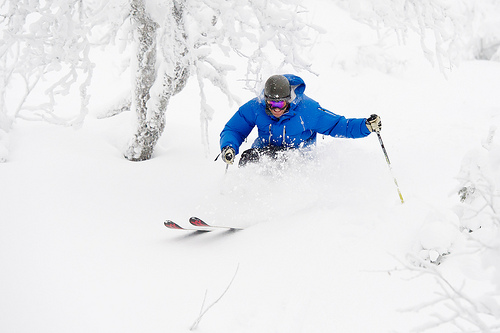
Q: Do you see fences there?
A: No, there are no fences.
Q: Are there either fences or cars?
A: No, there are no fences or cars.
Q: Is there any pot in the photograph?
A: No, there are no pots.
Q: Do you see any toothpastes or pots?
A: No, there are no pots or toothpastes.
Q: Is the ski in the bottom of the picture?
A: Yes, the ski is in the bottom of the image.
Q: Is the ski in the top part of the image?
A: No, the ski is in the bottom of the image.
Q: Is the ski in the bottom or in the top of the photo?
A: The ski is in the bottom of the image.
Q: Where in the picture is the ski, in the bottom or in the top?
A: The ski is in the bottom of the image.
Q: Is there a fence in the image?
A: No, there are no fences.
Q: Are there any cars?
A: No, there are no cars.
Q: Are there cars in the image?
A: No, there are no cars.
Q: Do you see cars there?
A: No, there are no cars.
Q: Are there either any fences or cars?
A: No, there are no cars or fences.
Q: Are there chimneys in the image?
A: No, there are no chimneys.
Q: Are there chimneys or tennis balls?
A: No, there are no chimneys or tennis balls.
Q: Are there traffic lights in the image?
A: No, there are no traffic lights.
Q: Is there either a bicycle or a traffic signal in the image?
A: No, there are no traffic lights or bicycles.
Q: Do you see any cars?
A: No, there are no cars.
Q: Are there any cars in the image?
A: No, there are no cars.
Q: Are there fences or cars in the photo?
A: No, there are no cars or fences.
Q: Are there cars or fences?
A: No, there are no cars or fences.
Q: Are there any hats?
A: Yes, there is a hat.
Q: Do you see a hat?
A: Yes, there is a hat.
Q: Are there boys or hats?
A: Yes, there is a hat.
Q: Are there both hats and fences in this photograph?
A: No, there is a hat but no fences.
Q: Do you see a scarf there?
A: No, there are no scarves.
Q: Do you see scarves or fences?
A: No, there are no scarves or fences.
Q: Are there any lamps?
A: No, there are no lamps.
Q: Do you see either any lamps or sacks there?
A: No, there are no lamps or sacks.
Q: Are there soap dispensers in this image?
A: No, there are no soap dispensers.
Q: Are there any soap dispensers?
A: No, there are no soap dispensers.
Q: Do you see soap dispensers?
A: No, there are no soap dispensers.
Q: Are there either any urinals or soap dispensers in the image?
A: No, there are no soap dispensers or urinals.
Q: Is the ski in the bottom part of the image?
A: Yes, the ski is in the bottom of the image.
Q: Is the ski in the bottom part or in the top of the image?
A: The ski is in the bottom of the image.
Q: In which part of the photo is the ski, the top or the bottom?
A: The ski is in the bottom of the image.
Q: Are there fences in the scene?
A: No, there are no fences.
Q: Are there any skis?
A: Yes, there are skis.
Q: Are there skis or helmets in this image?
A: Yes, there are skis.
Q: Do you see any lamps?
A: No, there are no lamps.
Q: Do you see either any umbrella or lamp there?
A: No, there are no lamps or umbrellas.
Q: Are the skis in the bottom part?
A: Yes, the skis are in the bottom of the image.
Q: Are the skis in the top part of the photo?
A: No, the skis are in the bottom of the image.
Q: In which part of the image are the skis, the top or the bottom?
A: The skis are in the bottom of the image.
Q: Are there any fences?
A: No, there are no fences.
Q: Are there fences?
A: No, there are no fences.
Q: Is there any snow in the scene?
A: Yes, there is snow.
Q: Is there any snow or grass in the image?
A: Yes, there is snow.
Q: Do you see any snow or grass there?
A: Yes, there is snow.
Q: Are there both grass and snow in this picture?
A: No, there is snow but no grass.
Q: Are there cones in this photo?
A: No, there are no cones.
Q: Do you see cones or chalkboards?
A: No, there are no cones or chalkboards.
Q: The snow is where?
A: The snow is on the ground.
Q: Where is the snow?
A: The snow is on the ground.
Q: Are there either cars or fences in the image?
A: No, there are no fences or cars.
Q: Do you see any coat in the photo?
A: Yes, there is a coat.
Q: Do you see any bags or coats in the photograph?
A: Yes, there is a coat.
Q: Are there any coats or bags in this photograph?
A: Yes, there is a coat.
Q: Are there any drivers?
A: No, there are no drivers.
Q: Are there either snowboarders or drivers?
A: No, there are no drivers or snowboarders.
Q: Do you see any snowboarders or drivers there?
A: No, there are no drivers or snowboarders.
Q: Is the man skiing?
A: Yes, the man is skiing.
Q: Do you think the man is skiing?
A: Yes, the man is skiing.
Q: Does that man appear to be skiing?
A: Yes, the man is skiing.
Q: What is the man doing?
A: The man is skiing.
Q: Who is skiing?
A: The man is skiing.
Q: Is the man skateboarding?
A: No, the man is skiing.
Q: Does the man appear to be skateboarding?
A: No, the man is skiing.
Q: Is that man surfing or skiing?
A: The man is skiing.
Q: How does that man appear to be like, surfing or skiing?
A: The man is skiing.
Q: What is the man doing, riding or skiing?
A: The man is skiing.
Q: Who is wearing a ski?
A: The man is wearing a ski.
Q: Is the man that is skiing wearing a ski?
A: Yes, the man is wearing a ski.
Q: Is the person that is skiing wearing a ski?
A: Yes, the man is wearing a ski.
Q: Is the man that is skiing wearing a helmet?
A: No, the man is wearing a ski.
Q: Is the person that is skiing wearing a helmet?
A: No, the man is wearing a ski.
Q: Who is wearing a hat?
A: The man is wearing a hat.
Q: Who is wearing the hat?
A: The man is wearing a hat.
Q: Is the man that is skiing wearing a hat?
A: Yes, the man is wearing a hat.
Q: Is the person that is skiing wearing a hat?
A: Yes, the man is wearing a hat.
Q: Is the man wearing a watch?
A: No, the man is wearing a hat.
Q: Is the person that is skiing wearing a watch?
A: No, the man is wearing a hat.